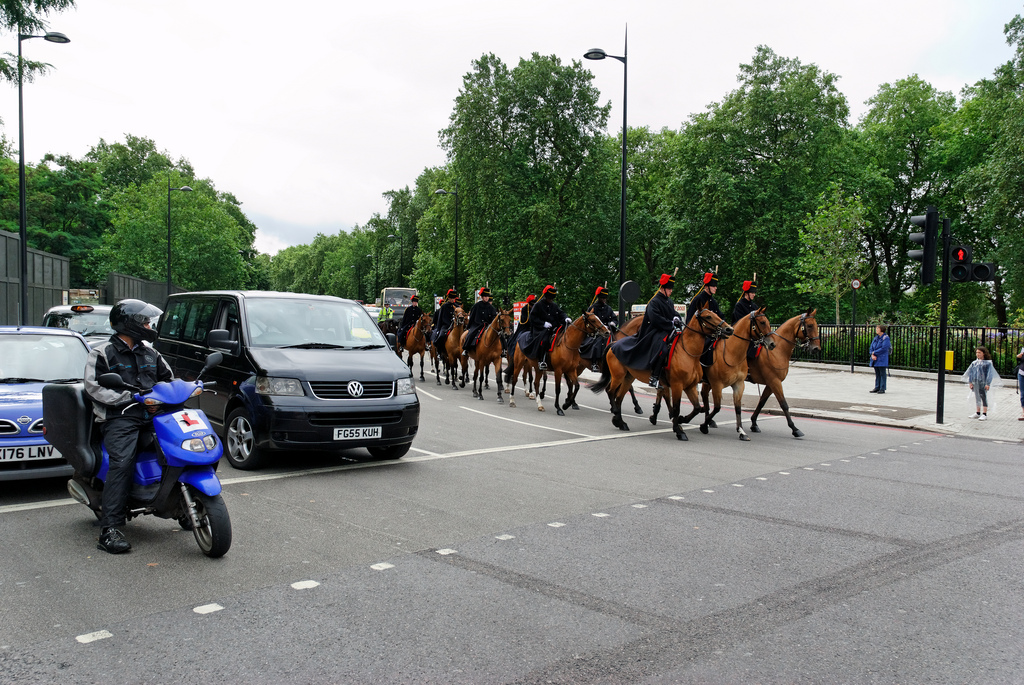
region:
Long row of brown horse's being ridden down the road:
[403, 281, 824, 437]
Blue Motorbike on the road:
[57, 326, 236, 554]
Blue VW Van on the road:
[147, 288, 419, 463]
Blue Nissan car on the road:
[0, 323, 98, 501]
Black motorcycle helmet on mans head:
[109, 297, 160, 340]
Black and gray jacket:
[83, 341, 176, 412]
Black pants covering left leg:
[103, 414, 133, 528]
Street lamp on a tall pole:
[19, 34, 70, 323]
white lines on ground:
[419, 486, 661, 584]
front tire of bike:
[163, 474, 268, 574]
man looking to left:
[73, 253, 254, 507]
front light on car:
[242, 339, 341, 442]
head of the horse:
[771, 285, 855, 377]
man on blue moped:
[38, 300, 232, 557]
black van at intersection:
[151, 282, 424, 469]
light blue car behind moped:
[0, 325, 96, 497]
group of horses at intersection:
[401, 265, 828, 442]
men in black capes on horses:
[404, 266, 822, 445]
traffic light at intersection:
[904, 205, 994, 421]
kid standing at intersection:
[958, 344, 1003, 421]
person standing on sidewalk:
[863, 322, 895, 395]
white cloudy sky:
[0, 2, 1022, 249]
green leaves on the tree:
[874, 148, 917, 221]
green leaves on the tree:
[743, 107, 804, 194]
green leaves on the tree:
[693, 212, 798, 255]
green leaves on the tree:
[629, 159, 678, 220]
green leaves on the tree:
[564, 206, 587, 220]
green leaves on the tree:
[482, 177, 581, 302]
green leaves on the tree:
[453, 189, 517, 259]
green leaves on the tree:
[371, 206, 499, 317]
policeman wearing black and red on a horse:
[598, 261, 734, 443]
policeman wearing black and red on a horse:
[671, 272, 771, 429]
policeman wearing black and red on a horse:
[576, 276, 646, 346]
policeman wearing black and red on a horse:
[460, 276, 514, 406]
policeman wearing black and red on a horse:
[421, 279, 469, 385]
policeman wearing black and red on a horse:
[403, 282, 430, 382]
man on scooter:
[24, 285, 236, 565]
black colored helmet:
[101, 292, 175, 337]